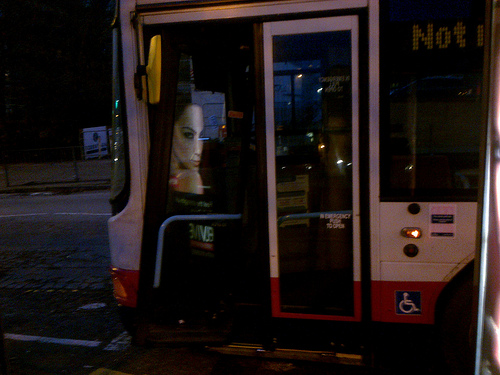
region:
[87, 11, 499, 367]
The bus is sitting at the stop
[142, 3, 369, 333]
The door to the bus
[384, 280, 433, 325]
A sign that shows handicap equipped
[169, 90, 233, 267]
The reflection of an ad in the window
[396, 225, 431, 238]
The light on the side of the bus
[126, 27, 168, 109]
The rear view mirror on the bus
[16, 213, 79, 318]
The street is made of asphalt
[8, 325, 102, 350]
The line in the road is white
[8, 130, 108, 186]
The gate on the side of the street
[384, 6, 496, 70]
The sign on the side of the bus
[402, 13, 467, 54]
yellow text on black sign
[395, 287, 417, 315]
blue and white handicap sticker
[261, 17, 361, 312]
door of the bus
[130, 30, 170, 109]
yellow side view mirror of bus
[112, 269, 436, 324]
red stripe on bottom of bus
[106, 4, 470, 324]
white and red bus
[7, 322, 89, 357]
white line painted on road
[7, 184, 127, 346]
road bus is traveling on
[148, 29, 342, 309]
reflection on bus window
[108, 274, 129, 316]
orange reflector on bus bumper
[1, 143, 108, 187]
A gray metal fence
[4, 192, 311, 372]
A dimly lit street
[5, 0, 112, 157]
A dark night with no stars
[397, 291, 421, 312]
A handicapped symbol in white and blue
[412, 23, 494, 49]
Part of a scrolling neon sign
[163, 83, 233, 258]
A faded poster of a woman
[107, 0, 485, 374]
An empty bus vehicle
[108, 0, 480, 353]
A red and white bus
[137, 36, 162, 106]
The side of a yellow bus mirror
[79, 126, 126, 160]
An illegible white advertisement sign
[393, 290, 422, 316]
a handicap sign on the bottom side of the bus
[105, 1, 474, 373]
a red and white transit bus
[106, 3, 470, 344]
the front left side of a transit bus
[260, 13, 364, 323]
the door on the left side of the transit bus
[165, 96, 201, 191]
a picture of Jennifer Lopez in the window of the bus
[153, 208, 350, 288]
blue metal rods on the transit bus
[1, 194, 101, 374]
a worn asphalt street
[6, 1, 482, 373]
a red and white bus on the paved street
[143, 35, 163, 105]
a yellow side view mirror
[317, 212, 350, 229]
"In Emergency Push To Open" written on the door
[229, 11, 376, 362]
the bus door is closed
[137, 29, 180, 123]
the side mirror is yellow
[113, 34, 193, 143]
the side mirror is yellow